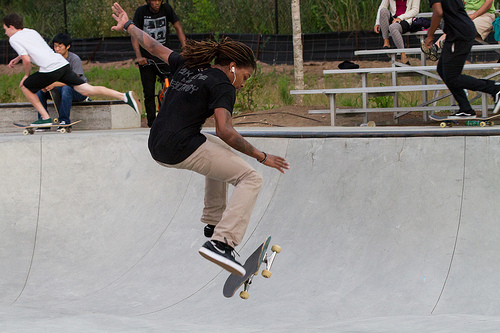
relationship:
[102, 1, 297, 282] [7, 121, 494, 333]
skateboarder in skateboard park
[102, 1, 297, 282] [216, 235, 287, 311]
skateboarder riding a skateboard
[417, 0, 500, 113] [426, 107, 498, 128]
skateboarder riding skateboard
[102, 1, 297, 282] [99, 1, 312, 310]
skateboarder doing a trick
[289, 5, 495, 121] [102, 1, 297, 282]
stands for observing skateboarders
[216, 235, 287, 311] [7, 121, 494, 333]
skateboard trick ramp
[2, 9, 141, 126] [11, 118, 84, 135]
person riding skateboard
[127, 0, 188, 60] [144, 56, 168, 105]
guy on bike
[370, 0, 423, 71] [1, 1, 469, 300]
lady watching skateboarders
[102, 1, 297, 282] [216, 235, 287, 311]
skateboarder rides skateboard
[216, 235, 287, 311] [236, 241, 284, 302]
skateboard with yellow wheels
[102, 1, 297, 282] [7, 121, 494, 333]
boy skateboarding on ramp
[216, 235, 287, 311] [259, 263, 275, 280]
skateboard seen wheel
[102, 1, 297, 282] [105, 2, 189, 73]
skater has left arm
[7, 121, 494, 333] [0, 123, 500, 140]
ramp seen edge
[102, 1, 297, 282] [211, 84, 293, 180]
boy has right arm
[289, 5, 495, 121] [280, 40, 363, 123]
bench sees a edge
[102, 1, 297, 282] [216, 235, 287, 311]
boy riding skateboard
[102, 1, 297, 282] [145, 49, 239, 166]
boy wearing black shirt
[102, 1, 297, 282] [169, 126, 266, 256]
boy wearing tan pants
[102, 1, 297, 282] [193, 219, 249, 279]
boy wearing white sneakers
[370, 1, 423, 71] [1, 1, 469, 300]
girl watching skateboarders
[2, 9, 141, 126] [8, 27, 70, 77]
boy wearing white shirt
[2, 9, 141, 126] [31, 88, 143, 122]
boy wearing green shoes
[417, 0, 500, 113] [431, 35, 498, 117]
boy wearing black pants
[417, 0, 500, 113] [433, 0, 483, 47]
boy wearing gray shirt